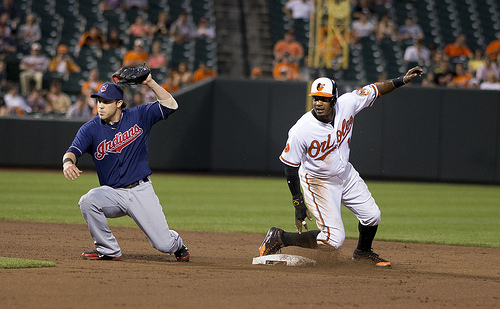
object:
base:
[248, 253, 319, 267]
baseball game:
[0, 0, 492, 309]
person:
[125, 38, 146, 64]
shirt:
[123, 50, 149, 65]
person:
[271, 34, 303, 57]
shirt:
[277, 41, 308, 57]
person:
[43, 45, 83, 74]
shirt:
[442, 42, 475, 55]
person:
[192, 63, 215, 83]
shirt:
[74, 33, 108, 49]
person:
[271, 53, 301, 82]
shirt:
[24, 56, 48, 70]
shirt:
[159, 80, 180, 94]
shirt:
[485, 41, 499, 55]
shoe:
[256, 226, 286, 259]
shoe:
[352, 244, 392, 267]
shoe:
[81, 248, 125, 260]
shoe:
[166, 241, 190, 262]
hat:
[308, 76, 339, 95]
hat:
[87, 83, 125, 101]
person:
[57, 70, 191, 260]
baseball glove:
[109, 64, 153, 83]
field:
[0, 163, 498, 307]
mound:
[0, 220, 499, 309]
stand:
[0, 7, 500, 93]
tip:
[384, 262, 393, 266]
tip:
[184, 257, 188, 260]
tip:
[81, 253, 90, 261]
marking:
[114, 59, 140, 78]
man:
[63, 44, 164, 247]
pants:
[79, 183, 182, 261]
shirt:
[274, 84, 381, 172]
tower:
[305, 0, 348, 66]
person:
[257, 66, 424, 274]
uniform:
[279, 84, 382, 249]